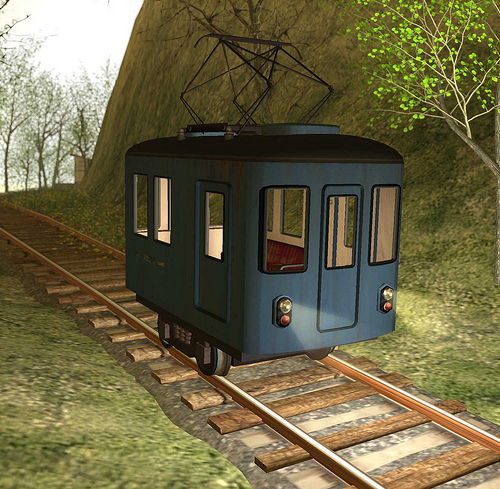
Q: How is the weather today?
A: It is cloudy.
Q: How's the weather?
A: It is cloudy.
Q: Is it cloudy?
A: Yes, it is cloudy.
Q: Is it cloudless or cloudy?
A: It is cloudy.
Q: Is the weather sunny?
A: No, it is cloudy.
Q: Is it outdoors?
A: Yes, it is outdoors.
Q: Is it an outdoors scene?
A: Yes, it is outdoors.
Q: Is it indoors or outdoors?
A: It is outdoors.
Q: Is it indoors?
A: No, it is outdoors.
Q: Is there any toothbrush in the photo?
A: No, there are no toothbrushes.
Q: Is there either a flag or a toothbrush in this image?
A: No, there are no toothbrushes or flags.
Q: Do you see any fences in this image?
A: No, there are no fences.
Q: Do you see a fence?
A: No, there are no fences.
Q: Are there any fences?
A: No, there are no fences.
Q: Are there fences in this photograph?
A: No, there are no fences.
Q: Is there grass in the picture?
A: Yes, there is grass.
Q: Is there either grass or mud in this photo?
A: Yes, there is grass.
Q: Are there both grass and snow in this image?
A: No, there is grass but no snow.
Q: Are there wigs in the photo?
A: No, there are no wigs.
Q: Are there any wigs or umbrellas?
A: No, there are no wigs or umbrellas.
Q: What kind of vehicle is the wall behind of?
A: The wall is behind the car.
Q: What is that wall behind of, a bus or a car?
A: The wall is behind a car.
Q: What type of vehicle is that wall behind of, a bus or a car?
A: The wall is behind a car.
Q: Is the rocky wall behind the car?
A: Yes, the wall is behind the car.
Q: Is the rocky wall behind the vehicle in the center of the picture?
A: Yes, the wall is behind the car.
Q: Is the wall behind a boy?
A: No, the wall is behind the car.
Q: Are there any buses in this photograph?
A: No, there are no buses.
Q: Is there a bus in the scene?
A: No, there are no buses.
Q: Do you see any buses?
A: No, there are no buses.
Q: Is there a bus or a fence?
A: No, there are no buses or fences.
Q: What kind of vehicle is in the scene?
A: The vehicle is a car.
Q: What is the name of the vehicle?
A: The vehicle is a car.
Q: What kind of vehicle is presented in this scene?
A: The vehicle is a car.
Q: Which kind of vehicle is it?
A: The vehicle is a car.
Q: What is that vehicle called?
A: This is a car.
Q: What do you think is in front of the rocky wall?
A: The car is in front of the wall.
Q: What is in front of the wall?
A: The car is in front of the wall.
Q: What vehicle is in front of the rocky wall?
A: The vehicle is a car.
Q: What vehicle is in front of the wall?
A: The vehicle is a car.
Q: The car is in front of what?
A: The car is in front of the wall.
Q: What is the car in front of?
A: The car is in front of the wall.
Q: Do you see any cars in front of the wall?
A: Yes, there is a car in front of the wall.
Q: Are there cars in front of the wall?
A: Yes, there is a car in front of the wall.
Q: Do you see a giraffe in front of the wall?
A: No, there is a car in front of the wall.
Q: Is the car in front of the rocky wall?
A: Yes, the car is in front of the wall.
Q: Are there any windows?
A: Yes, there is a window.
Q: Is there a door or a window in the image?
A: Yes, there is a window.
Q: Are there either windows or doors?
A: Yes, there is a window.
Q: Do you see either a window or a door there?
A: Yes, there is a window.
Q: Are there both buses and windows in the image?
A: No, there is a window but no buses.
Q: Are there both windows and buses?
A: No, there is a window but no buses.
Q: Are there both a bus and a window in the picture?
A: No, there is a window but no buses.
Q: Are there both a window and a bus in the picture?
A: No, there is a window but no buses.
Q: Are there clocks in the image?
A: No, there are no clocks.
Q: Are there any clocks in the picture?
A: No, there are no clocks.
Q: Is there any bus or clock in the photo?
A: No, there are no clocks or buses.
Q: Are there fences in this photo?
A: No, there are no fences.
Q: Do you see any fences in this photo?
A: No, there are no fences.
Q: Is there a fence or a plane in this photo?
A: No, there are no fences or airplanes.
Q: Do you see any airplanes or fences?
A: No, there are no fences or airplanes.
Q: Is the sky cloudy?
A: Yes, the sky is cloudy.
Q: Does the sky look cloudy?
A: Yes, the sky is cloudy.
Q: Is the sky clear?
A: No, the sky is cloudy.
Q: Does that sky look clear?
A: No, the sky is cloudy.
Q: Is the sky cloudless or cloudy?
A: The sky is cloudy.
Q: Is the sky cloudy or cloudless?
A: The sky is cloudy.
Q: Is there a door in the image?
A: Yes, there is a door.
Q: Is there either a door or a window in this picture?
A: Yes, there is a door.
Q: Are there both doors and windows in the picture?
A: Yes, there are both a door and a window.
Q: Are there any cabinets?
A: No, there are no cabinets.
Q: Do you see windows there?
A: Yes, there is a window.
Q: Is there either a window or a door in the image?
A: Yes, there is a window.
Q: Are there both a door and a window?
A: Yes, there are both a window and a door.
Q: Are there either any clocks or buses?
A: No, there are no clocks or buses.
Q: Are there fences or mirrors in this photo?
A: No, there are no fences or mirrors.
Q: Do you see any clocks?
A: No, there are no clocks.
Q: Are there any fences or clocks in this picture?
A: No, there are no clocks or fences.